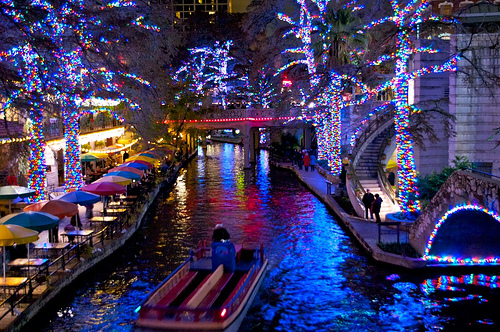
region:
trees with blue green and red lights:
[1, 0, 481, 212]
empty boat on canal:
[134, 221, 272, 330]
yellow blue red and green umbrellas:
[0, 146, 168, 250]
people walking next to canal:
[364, 186, 381, 221]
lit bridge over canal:
[405, 167, 499, 266]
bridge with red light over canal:
[157, 95, 315, 155]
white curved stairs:
[345, 91, 437, 217]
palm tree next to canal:
[310, 0, 371, 200]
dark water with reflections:
[32, 146, 496, 330]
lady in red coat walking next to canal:
[303, 147, 312, 170]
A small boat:
[136, 222, 273, 329]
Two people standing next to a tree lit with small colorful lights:
[358, 13, 426, 224]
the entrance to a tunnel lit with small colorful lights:
[408, 164, 498, 267]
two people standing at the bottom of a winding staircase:
[353, 115, 396, 222]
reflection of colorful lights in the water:
[407, 265, 497, 318]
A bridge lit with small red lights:
[186, 103, 319, 143]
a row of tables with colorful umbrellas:
[0, 126, 181, 304]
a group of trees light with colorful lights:
[173, 34, 273, 107]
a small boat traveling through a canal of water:
[135, 146, 307, 329]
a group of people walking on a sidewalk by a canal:
[278, 143, 321, 179]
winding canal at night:
[23, 134, 405, 329]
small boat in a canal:
[131, 225, 286, 330]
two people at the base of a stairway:
[363, 185, 384, 222]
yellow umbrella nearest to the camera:
[1, 220, 43, 286]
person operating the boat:
[210, 217, 233, 246]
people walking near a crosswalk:
[293, 142, 319, 175]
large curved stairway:
[341, 93, 411, 224]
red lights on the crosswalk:
[147, 113, 321, 123]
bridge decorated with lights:
[403, 164, 499, 264]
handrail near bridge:
[371, 218, 413, 255]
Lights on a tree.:
[278, 7, 359, 174]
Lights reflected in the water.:
[185, 160, 292, 215]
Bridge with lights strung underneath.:
[420, 187, 496, 288]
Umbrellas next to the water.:
[0, 105, 195, 270]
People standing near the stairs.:
[345, 155, 390, 230]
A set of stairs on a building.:
[330, 97, 426, 187]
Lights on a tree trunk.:
[55, 106, 90, 181]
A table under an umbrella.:
[80, 175, 130, 222]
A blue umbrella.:
[1, 207, 61, 224]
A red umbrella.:
[77, 173, 132, 198]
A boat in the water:
[131, 226, 285, 329]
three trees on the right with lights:
[264, 2, 444, 211]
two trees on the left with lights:
[6, 2, 90, 217]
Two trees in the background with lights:
[165, 29, 259, 112]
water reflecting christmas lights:
[14, 127, 491, 329]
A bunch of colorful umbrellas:
[2, 131, 176, 253]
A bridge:
[398, 165, 498, 271]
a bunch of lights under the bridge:
[420, 197, 499, 276]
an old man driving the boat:
[210, 218, 230, 256]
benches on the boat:
[147, 252, 239, 319]